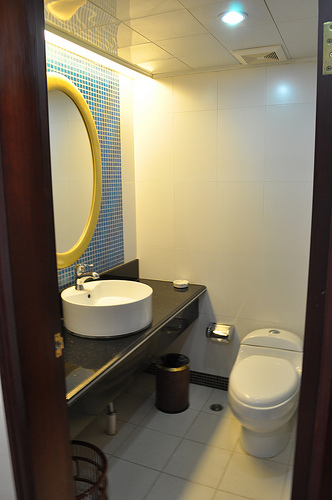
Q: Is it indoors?
A: Yes, it is indoors.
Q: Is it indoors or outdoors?
A: It is indoors.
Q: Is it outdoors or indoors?
A: It is indoors.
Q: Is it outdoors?
A: No, it is indoors.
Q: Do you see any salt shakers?
A: No, there are no salt shakers.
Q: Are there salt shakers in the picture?
A: No, there are no salt shakers.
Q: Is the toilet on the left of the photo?
A: No, the toilet is on the right of the image.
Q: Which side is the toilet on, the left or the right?
A: The toilet is on the right of the image.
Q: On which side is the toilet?
A: The toilet is on the right of the image.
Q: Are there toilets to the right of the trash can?
A: Yes, there is a toilet to the right of the trash can.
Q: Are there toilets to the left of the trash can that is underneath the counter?
A: No, the toilet is to the right of the garbage can.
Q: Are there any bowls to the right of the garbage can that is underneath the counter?
A: No, there is a toilet to the right of the garbage bin.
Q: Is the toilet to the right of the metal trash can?
A: Yes, the toilet is to the right of the trashcan.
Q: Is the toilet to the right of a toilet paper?
A: No, the toilet is to the right of the trashcan.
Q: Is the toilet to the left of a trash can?
A: No, the toilet is to the right of a trash can.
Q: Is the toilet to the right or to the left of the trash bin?
A: The toilet is to the right of the trash bin.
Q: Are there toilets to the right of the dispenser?
A: Yes, there is a toilet to the right of the dispenser.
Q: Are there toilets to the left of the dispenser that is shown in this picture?
A: No, the toilet is to the right of the dispenser.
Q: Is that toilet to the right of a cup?
A: No, the toilet is to the right of the dispenser.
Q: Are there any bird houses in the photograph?
A: No, there are no bird houses.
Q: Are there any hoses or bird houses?
A: No, there are no bird houses or hoses.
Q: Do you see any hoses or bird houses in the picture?
A: No, there are no bird houses or hoses.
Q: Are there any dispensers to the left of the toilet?
A: Yes, there is a dispenser to the left of the toilet.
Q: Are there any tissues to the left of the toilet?
A: No, there is a dispenser to the left of the toilet.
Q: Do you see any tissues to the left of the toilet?
A: No, there is a dispenser to the left of the toilet.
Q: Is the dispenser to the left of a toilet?
A: Yes, the dispenser is to the left of a toilet.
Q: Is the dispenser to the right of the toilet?
A: No, the dispenser is to the left of the toilet.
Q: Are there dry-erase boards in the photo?
A: No, there are no dry-erase boards.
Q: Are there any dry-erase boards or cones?
A: No, there are no dry-erase boards or cones.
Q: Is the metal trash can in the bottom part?
A: Yes, the trash bin is in the bottom of the image.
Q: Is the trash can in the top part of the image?
A: No, the trash can is in the bottom of the image.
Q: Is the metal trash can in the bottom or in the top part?
A: The garbage can is in the bottom of the image.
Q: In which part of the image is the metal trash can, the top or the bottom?
A: The garbage can is in the bottom of the image.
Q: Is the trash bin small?
A: Yes, the trash bin is small.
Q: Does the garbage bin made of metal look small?
A: Yes, the trash can is small.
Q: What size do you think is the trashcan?
A: The trashcan is small.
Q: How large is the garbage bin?
A: The garbage bin is small.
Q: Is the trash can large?
A: No, the trash can is small.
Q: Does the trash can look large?
A: No, the trash can is small.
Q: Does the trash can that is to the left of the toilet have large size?
A: No, the garbage bin is small.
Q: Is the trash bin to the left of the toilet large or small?
A: The garbage can is small.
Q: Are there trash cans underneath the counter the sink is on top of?
A: Yes, there is a trash can underneath the counter.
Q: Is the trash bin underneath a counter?
A: Yes, the trash bin is underneath a counter.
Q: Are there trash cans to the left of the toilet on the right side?
A: Yes, there is a trash can to the left of the toilet.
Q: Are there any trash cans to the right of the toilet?
A: No, the trash can is to the left of the toilet.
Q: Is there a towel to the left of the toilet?
A: No, there is a trash can to the left of the toilet.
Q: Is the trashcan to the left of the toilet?
A: Yes, the trashcan is to the left of the toilet.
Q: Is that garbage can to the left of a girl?
A: No, the garbage can is to the left of the toilet.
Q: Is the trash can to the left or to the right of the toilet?
A: The trash can is to the left of the toilet.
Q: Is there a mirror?
A: Yes, there is a mirror.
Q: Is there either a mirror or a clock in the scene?
A: Yes, there is a mirror.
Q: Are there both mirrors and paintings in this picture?
A: No, there is a mirror but no paintings.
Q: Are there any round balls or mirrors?
A: Yes, there is a round mirror.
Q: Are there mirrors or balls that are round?
A: Yes, the mirror is round.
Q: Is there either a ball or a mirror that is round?
A: Yes, the mirror is round.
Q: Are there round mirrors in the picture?
A: Yes, there is a round mirror.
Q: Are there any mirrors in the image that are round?
A: Yes, there is a mirror that is round.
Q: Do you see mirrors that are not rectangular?
A: Yes, there is a round mirror.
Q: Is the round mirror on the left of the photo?
A: Yes, the mirror is on the left of the image.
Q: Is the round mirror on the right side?
A: No, the mirror is on the left of the image.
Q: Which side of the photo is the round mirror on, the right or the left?
A: The mirror is on the left of the image.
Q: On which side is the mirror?
A: The mirror is on the left of the image.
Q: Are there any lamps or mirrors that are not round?
A: No, there is a mirror but it is round.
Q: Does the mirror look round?
A: Yes, the mirror is round.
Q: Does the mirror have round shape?
A: Yes, the mirror is round.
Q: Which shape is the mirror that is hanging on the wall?
A: The mirror is round.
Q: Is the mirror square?
A: No, the mirror is round.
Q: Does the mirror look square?
A: No, the mirror is round.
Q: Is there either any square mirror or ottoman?
A: No, there is a mirror but it is round.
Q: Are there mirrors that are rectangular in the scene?
A: No, there is a mirror but it is round.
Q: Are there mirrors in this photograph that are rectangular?
A: No, there is a mirror but it is round.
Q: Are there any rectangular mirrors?
A: No, there is a mirror but it is round.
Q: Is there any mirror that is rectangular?
A: No, there is a mirror but it is round.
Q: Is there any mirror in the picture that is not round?
A: No, there is a mirror but it is round.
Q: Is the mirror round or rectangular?
A: The mirror is round.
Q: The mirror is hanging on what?
A: The mirror is hanging on the wall.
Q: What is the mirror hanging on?
A: The mirror is hanging on the wall.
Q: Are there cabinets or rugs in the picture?
A: No, there are no cabinets or rugs.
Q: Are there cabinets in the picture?
A: No, there are no cabinets.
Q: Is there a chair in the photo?
A: No, there are no chairs.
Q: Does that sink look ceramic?
A: Yes, the sink is ceramic.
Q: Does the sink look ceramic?
A: Yes, the sink is ceramic.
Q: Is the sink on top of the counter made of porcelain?
A: Yes, the sink is made of porcelain.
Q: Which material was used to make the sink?
A: The sink is made of porcelain.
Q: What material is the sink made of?
A: The sink is made of porcelain.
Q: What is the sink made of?
A: The sink is made of porcelain.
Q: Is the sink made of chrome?
A: No, the sink is made of porcelain.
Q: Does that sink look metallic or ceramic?
A: The sink is ceramic.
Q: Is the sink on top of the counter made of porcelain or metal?
A: The sink is made of porcelain.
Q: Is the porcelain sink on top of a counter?
A: Yes, the sink is on top of a counter.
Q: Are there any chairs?
A: No, there are no chairs.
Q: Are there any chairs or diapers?
A: No, there are no chairs or diapers.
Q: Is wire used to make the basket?
A: Yes, the basket is made of wire.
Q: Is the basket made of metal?
A: No, the basket is made of wire.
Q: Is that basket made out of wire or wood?
A: The basket is made of wire.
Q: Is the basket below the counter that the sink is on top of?
A: Yes, the basket is below the counter.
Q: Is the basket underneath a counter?
A: Yes, the basket is underneath a counter.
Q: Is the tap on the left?
A: Yes, the tap is on the left of the image.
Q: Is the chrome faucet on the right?
A: No, the faucet is on the left of the image.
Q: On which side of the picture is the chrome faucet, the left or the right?
A: The faucet is on the left of the image.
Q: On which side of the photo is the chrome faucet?
A: The tap is on the left of the image.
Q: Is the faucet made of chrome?
A: Yes, the faucet is made of chrome.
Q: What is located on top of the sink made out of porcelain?
A: The faucet is on top of the sink.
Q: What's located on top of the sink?
A: The faucet is on top of the sink.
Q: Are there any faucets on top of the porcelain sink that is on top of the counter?
A: Yes, there is a faucet on top of the sink.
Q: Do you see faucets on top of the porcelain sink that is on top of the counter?
A: Yes, there is a faucet on top of the sink.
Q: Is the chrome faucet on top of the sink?
A: Yes, the tap is on top of the sink.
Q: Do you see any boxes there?
A: No, there are no boxes.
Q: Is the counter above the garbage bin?
A: Yes, the counter is above the garbage bin.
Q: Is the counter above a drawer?
A: No, the counter is above the garbage bin.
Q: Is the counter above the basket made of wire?
A: Yes, the counter is above the basket.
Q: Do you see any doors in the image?
A: Yes, there is a door.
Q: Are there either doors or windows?
A: Yes, there is a door.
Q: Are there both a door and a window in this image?
A: No, there is a door but no windows.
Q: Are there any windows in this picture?
A: No, there are no windows.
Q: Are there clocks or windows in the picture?
A: No, there are no windows or clocks.